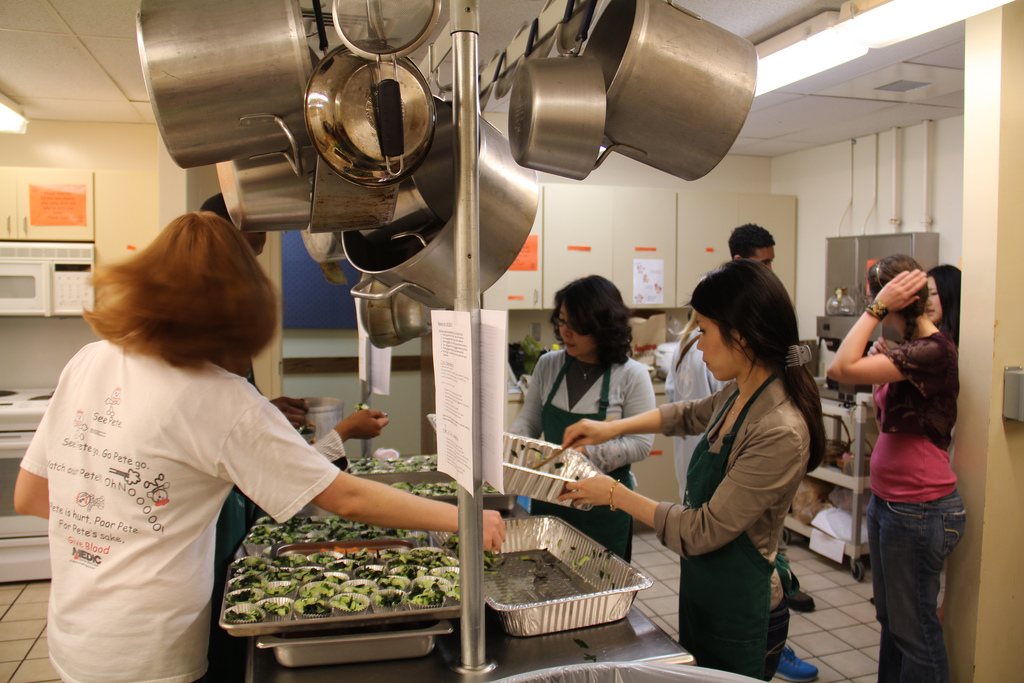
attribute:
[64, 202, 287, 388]
hair — reddish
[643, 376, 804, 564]
shirt — brown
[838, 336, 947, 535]
shirt — pink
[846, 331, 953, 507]
t-shirt — white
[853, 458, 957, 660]
jeans — blue